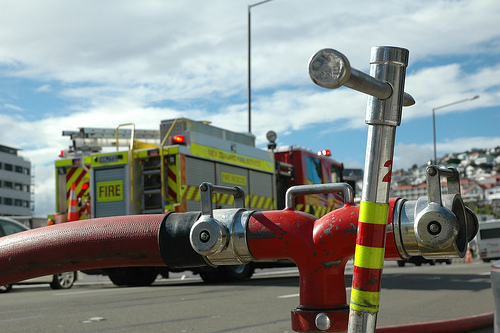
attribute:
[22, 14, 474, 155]
clouds — in the sky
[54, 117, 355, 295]
fire truck — red, yellow, driving, moving, on the road, gray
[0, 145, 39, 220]
building — concrete, white, near the road, multi-storied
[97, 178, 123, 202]
sign — yellow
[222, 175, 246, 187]
sign — yellow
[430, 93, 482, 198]
pole — metal, grey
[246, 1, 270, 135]
pole — on fire truck, grey, metal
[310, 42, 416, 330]
pole — metal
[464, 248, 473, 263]
cone — yellow, white, orange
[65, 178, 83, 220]
cone — orange, white, on fire truck, yellow, on back of truck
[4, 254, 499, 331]
street — clear, grey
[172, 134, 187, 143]
light — red, on back of truck, on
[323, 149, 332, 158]
light — on, red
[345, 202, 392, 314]
tape — red, yellow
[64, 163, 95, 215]
stripes — red, yellow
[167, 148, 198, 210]
stripes — red, yellow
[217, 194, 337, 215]
stripes — red, yellow, on the truck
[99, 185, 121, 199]
lettering — red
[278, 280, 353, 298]
line — white, on the ground, painted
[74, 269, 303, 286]
line — white, on the ground, painted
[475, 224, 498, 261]
van — white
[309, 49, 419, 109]
screw — long, silver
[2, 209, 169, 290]
fire hose — attached, red, connected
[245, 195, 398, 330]
pipe — red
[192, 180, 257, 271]
connector — metal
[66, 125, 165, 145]
ladder — on top of truck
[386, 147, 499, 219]
houses — on the hill, covered with houses